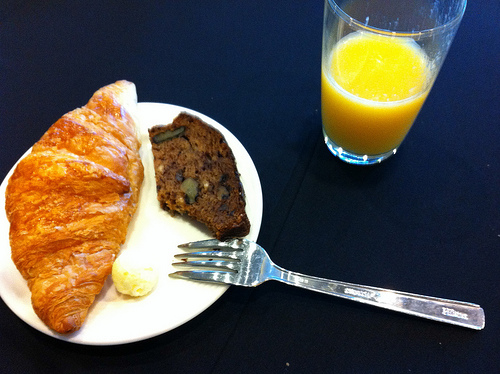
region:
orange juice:
[318, 31, 428, 158]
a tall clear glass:
[323, 0, 466, 167]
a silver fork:
[166, 235, 488, 332]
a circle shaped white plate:
[0, 99, 265, 344]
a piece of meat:
[140, 111, 256, 240]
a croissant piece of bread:
[4, 71, 149, 334]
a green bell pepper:
[180, 176, 199, 203]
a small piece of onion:
[155, 161, 167, 175]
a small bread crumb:
[276, 354, 298, 370]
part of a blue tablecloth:
[0, 3, 327, 103]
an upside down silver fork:
[170, 238, 485, 352]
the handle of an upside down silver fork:
[275, 256, 482, 346]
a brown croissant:
[12, 83, 155, 331]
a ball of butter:
[112, 248, 151, 292]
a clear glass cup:
[320, 2, 465, 167]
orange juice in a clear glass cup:
[322, 33, 423, 148]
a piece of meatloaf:
[152, 116, 239, 231]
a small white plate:
[1, 82, 265, 343]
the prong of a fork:
[173, 266, 231, 283]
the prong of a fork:
[174, 256, 241, 271]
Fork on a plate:
[172, 226, 489, 346]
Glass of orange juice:
[310, 2, 460, 169]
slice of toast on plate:
[157, 102, 263, 256]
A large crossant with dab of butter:
[23, 71, 145, 331]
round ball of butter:
[106, 241, 168, 306]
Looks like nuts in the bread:
[149, 101, 254, 251]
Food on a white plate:
[7, 66, 275, 343]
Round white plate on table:
[18, 89, 278, 345]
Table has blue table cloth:
[2, 6, 494, 355]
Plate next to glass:
[10, 57, 449, 289]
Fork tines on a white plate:
[165, 237, 269, 285]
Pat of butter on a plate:
[112, 249, 158, 296]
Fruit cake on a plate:
[143, 110, 251, 237]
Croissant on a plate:
[9, 79, 126, 341]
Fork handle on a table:
[275, 262, 487, 335]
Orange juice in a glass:
[308, 50, 425, 167]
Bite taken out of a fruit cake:
[156, 192, 223, 242]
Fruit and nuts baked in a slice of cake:
[178, 174, 204, 204]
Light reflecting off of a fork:
[376, 283, 402, 308]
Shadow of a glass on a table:
[291, 135, 401, 195]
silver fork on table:
[182, 238, 479, 333]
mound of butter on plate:
[111, 257, 158, 308]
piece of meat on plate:
[148, 116, 245, 243]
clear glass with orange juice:
[322, 17, 420, 203]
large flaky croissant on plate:
[10, 72, 101, 330]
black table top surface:
[183, 47, 273, 116]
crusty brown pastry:
[33, 163, 100, 226]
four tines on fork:
[169, 235, 226, 283]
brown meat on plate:
[151, 117, 248, 229]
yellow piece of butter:
[113, 240, 163, 305]